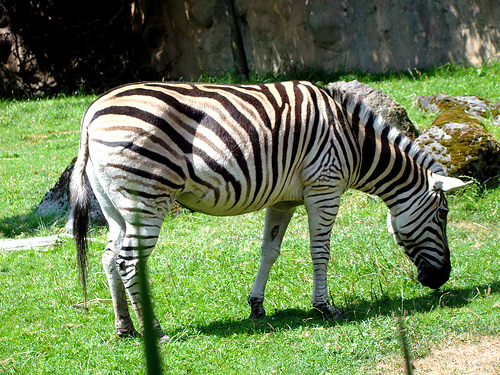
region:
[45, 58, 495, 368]
zebra standing in grass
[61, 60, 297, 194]
black and white zebra stripes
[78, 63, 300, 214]
zebra with black, white, and brown stripes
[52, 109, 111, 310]
bushy zebra tail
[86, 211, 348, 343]
striped zebra legs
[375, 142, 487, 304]
stripes on zebra's face and ears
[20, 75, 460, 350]
zebra eating green grass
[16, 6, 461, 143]
rocky walls behind zebra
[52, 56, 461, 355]
zebra lowering head to eat grass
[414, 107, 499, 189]
A rock covered in moss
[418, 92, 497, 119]
A rock covered in moss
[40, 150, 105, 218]
A rock covered in moss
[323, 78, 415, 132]
A large rock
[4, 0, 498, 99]
A large stone wall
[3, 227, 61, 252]
A flat stone on the ground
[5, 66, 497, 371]
A grassy field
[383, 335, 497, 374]
A patch of brown grass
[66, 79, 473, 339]
A zebra grazing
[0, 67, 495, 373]
A grassy landscape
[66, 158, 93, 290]
the zebras tail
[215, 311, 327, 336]
a shadow on the ground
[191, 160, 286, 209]
the zebras belly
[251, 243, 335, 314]
The zebras legs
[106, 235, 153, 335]
the zebras back legs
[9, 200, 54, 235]
a shadow on the ground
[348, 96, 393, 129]
hair on the zebra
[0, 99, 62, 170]
a field of green grass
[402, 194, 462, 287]
the zebra is looking down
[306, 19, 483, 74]
a shadow on the wall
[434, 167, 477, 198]
an ear of a zebra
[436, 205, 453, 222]
an eye of a zebra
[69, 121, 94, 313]
the tail of a zebra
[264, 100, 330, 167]
the stripes on a zebra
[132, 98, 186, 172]
the fur of a zebra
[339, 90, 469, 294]
a zebra eating grass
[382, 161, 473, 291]
the head of a zebra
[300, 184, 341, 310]
the front leg of a zebra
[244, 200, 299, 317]
the front leg of a zebra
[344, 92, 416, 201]
the neck of a zebra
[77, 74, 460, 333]
black and white zebra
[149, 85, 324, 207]
black and white stripes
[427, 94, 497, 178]
green moss growing on rock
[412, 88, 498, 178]
rock on green grass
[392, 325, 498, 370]
patch of dirt in grass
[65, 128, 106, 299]
black and white tail of zebra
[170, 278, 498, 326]
shadow of zebra in grass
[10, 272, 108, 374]
lush green grass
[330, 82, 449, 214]
black and white mane of zebra